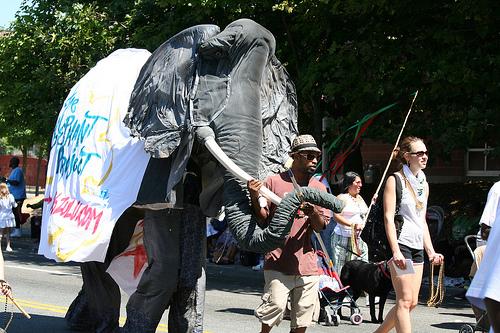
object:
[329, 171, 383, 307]
woman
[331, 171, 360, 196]
hair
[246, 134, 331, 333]
guy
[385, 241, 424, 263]
black shorts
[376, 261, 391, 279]
collar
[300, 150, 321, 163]
sunglasses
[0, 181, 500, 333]
ground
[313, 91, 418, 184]
streamer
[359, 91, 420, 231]
pole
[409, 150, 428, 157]
sunglasses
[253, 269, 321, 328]
shorts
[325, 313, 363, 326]
front wheels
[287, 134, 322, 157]
hat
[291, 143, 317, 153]
stripe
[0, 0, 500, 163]
green tree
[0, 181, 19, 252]
child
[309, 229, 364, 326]
stroller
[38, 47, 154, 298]
banner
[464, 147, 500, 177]
window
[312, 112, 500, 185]
building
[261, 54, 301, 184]
left ear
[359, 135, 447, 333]
girl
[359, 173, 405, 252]
bag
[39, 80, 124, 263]
sign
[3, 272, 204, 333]
street marking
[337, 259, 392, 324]
black dog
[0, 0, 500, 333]
afternoon parade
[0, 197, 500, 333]
street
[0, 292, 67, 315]
line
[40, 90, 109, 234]
letters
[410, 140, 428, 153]
shades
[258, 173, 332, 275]
shirt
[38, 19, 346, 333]
elephant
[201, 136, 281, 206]
tusk